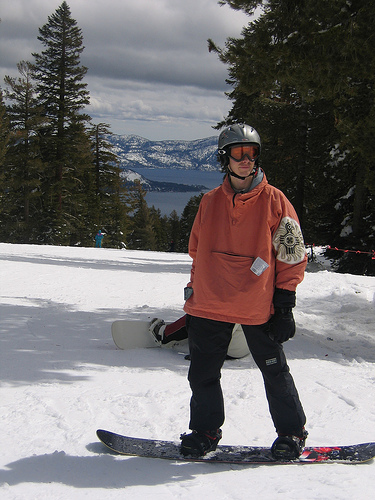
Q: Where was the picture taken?
A: The ski park.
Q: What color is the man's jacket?
A: Red.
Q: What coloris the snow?
A: White.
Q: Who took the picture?
A: A cousin.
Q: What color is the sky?
A: Grey.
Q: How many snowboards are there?
A: Two.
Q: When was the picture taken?
A: Winter.